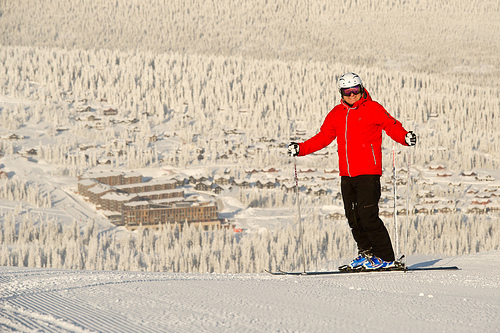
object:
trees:
[452, 9, 476, 77]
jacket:
[296, 88, 408, 176]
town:
[71, 168, 495, 226]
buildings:
[78, 171, 222, 231]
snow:
[4, 256, 494, 331]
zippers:
[342, 101, 352, 176]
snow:
[79, 167, 213, 209]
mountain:
[1, 250, 500, 333]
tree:
[209, 224, 229, 240]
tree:
[128, 248, 142, 269]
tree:
[176, 252, 186, 269]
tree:
[242, 244, 256, 274]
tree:
[179, 217, 190, 234]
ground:
[3, 254, 497, 331]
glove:
[405, 133, 417, 146]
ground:
[318, 94, 353, 126]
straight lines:
[9, 304, 112, 331]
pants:
[340, 173, 396, 263]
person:
[287, 72, 417, 270]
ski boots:
[338, 252, 375, 269]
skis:
[279, 266, 459, 275]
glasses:
[338, 89, 361, 97]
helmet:
[336, 72, 363, 91]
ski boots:
[354, 255, 405, 270]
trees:
[0, 199, 40, 264]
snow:
[0, 1, 20, 36]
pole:
[294, 156, 306, 274]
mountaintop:
[11, 253, 482, 328]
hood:
[361, 86, 372, 101]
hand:
[286, 142, 300, 157]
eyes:
[352, 88, 362, 95]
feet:
[352, 255, 400, 269]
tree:
[236, 169, 263, 207]